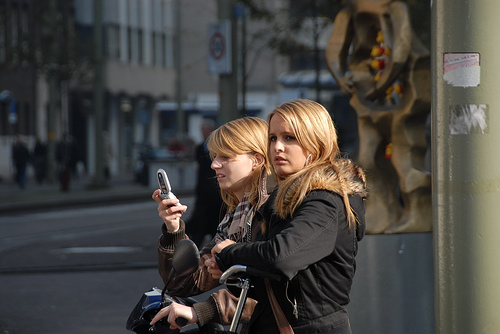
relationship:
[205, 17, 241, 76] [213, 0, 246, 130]
sign on post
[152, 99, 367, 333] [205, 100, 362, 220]
girl have hair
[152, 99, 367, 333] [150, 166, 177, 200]
girl holding phone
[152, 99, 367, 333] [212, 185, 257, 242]
girl wearing scarf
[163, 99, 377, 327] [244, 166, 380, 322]
girl wearing jacket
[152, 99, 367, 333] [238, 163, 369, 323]
girl wearing jacket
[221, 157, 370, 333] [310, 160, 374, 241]
coat has hood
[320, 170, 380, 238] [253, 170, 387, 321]
hood on jacket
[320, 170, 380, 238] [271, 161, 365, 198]
hood has trim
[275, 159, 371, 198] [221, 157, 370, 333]
trim on coat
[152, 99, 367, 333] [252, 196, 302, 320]
girl has strap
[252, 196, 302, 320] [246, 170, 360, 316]
strap across body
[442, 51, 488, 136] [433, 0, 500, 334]
sticker pealed pole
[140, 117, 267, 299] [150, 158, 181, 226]
woman looking phone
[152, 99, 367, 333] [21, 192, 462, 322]
girl looking down street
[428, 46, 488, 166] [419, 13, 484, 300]
sticker on pole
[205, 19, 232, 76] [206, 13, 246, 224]
sign on post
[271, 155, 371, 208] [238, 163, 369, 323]
fur lining of jacket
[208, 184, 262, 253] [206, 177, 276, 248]
fabric of shirt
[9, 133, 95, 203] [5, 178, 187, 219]
people walking on sidewalk